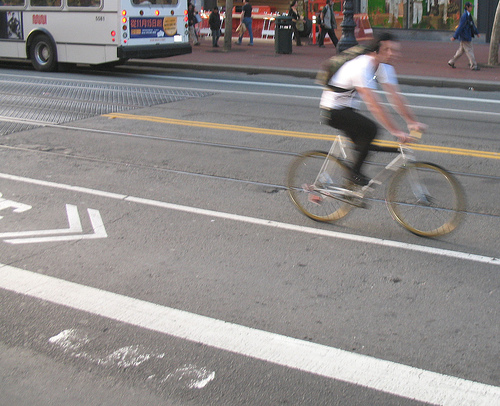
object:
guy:
[315, 34, 427, 190]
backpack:
[314, 42, 377, 91]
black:
[318, 105, 379, 174]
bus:
[1, 0, 195, 73]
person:
[445, 2, 488, 72]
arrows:
[0, 199, 112, 250]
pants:
[449, 36, 479, 70]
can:
[273, 15, 296, 55]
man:
[234, 0, 257, 48]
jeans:
[237, 15, 254, 45]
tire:
[26, 29, 60, 72]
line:
[94, 106, 500, 162]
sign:
[352, 13, 376, 40]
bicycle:
[284, 119, 472, 241]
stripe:
[2, 77, 499, 270]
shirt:
[317, 52, 401, 113]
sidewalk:
[186, 39, 500, 90]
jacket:
[453, 12, 481, 44]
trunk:
[487, 0, 499, 72]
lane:
[0, 171, 499, 403]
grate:
[0, 71, 226, 138]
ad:
[128, 15, 177, 39]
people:
[208, 6, 223, 48]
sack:
[317, 40, 369, 98]